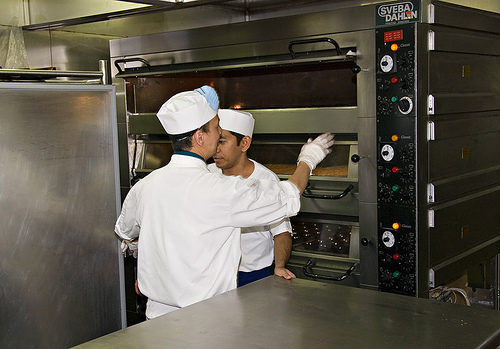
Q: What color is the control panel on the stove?
A: Black.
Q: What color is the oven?
A: Silver.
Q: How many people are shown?
A: Two.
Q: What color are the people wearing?
A: White.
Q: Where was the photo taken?
A: In a commercial kitchen.